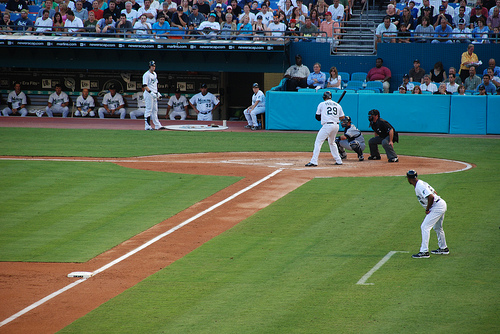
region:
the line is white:
[376, 248, 387, 279]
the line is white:
[371, 263, 383, 282]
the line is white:
[364, 260, 378, 285]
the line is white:
[367, 265, 377, 282]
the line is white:
[357, 271, 372, 291]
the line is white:
[379, 257, 384, 277]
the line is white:
[379, 253, 391, 278]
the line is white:
[367, 257, 387, 291]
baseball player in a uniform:
[301, 85, 351, 170]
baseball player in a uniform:
[401, 166, 455, 262]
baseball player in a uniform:
[137, 59, 163, 133]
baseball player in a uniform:
[237, 78, 272, 130]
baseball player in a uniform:
[186, 82, 221, 124]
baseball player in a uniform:
[163, 83, 190, 123]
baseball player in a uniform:
[95, 78, 126, 123]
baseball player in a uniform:
[73, 85, 96, 120]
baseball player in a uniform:
[45, 81, 74, 118]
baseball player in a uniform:
[0, 81, 27, 119]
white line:
[108, 207, 195, 272]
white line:
[48, 220, 156, 301]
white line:
[85, 200, 257, 325]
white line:
[158, 195, 239, 286]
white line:
[140, 200, 221, 332]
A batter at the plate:
[305, 84, 345, 174]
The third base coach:
[391, 163, 456, 265]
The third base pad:
[62, 267, 97, 281]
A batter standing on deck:
[136, 55, 173, 137]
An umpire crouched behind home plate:
[360, 103, 400, 162]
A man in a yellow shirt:
[459, 40, 482, 77]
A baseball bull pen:
[1, 39, 303, 140]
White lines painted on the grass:
[349, 232, 414, 300]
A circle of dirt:
[105, 131, 476, 193]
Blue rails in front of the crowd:
[0, 20, 333, 49]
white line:
[131, 226, 166, 262]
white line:
[122, 226, 187, 283]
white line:
[113, 222, 209, 302]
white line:
[102, 227, 168, 290]